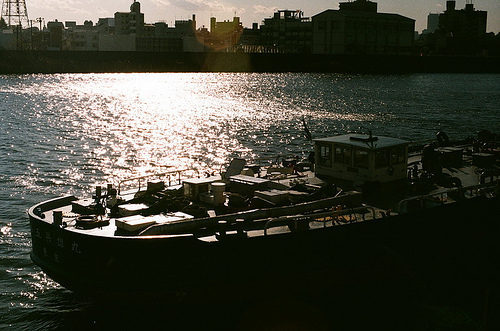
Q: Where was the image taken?
A: It was taken at the river.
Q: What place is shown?
A: It is a river.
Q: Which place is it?
A: It is a river.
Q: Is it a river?
A: Yes, it is a river.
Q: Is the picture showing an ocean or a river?
A: It is showing a river.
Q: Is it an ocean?
A: No, it is a river.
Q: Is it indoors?
A: Yes, it is indoors.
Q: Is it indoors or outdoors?
A: It is indoors.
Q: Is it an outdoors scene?
A: No, it is indoors.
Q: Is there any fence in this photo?
A: No, there are no fences.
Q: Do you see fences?
A: No, there are no fences.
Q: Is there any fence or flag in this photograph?
A: No, there are no fences or flags.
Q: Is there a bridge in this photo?
A: No, there are no bridges.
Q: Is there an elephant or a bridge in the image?
A: No, there are no bridges or elephants.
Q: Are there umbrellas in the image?
A: No, there are no umbrellas.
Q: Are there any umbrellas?
A: No, there are no umbrellas.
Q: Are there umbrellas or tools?
A: No, there are no umbrellas or tools.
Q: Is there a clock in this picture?
A: No, there are no clocks.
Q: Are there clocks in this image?
A: No, there are no clocks.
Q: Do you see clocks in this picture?
A: No, there are no clocks.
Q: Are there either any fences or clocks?
A: No, there are no clocks or fences.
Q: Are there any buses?
A: No, there are no buses.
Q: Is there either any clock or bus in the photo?
A: No, there are no buses or clocks.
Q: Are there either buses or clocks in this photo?
A: No, there are no buses or clocks.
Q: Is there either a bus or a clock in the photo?
A: No, there are no buses or clocks.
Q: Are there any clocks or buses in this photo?
A: No, there are no buses or clocks.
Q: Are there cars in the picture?
A: No, there are no cars.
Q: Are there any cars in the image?
A: No, there are no cars.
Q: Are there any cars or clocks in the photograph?
A: No, there are no cars or clocks.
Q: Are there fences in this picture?
A: No, there are no fences.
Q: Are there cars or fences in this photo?
A: No, there are no fences or cars.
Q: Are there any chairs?
A: No, there are no chairs.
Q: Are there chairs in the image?
A: No, there are no chairs.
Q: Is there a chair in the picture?
A: No, there are no chairs.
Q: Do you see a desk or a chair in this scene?
A: No, there are no chairs or desks.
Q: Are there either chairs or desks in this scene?
A: No, there are no chairs or desks.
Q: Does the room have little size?
A: Yes, the room is little.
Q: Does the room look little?
A: Yes, the room is little.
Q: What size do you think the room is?
A: The room is little.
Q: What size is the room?
A: The room is little.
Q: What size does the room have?
A: The room has little size.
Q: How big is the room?
A: The room is little.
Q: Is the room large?
A: No, the room is little.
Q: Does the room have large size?
A: No, the room is little.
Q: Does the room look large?
A: No, the room is little.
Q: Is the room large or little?
A: The room is little.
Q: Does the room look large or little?
A: The room is little.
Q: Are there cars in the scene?
A: No, there are no cars.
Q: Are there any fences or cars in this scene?
A: No, there are no cars or fences.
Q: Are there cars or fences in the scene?
A: No, there are no cars or fences.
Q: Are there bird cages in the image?
A: No, there are no bird cages.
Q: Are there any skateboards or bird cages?
A: No, there are no bird cages or skateboards.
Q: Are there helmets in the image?
A: No, there are no helmets.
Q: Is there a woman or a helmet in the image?
A: No, there are no helmets or women.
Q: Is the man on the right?
A: Yes, the man is on the right of the image.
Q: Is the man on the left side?
A: No, the man is on the right of the image.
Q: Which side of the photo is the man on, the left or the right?
A: The man is on the right of the image.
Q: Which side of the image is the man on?
A: The man is on the right of the image.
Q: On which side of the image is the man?
A: The man is on the right of the image.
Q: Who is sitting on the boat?
A: The man is sitting on the boat.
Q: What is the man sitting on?
A: The man is sitting on the boat.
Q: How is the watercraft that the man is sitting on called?
A: The watercraft is a boat.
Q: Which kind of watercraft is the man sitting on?
A: The man is sitting on the boat.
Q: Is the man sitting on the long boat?
A: Yes, the man is sitting on the boat.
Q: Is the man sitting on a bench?
A: No, the man is sitting on the boat.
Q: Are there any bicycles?
A: No, there are no bicycles.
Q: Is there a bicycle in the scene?
A: No, there are no bicycles.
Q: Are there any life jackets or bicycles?
A: No, there are no bicycles or life jackets.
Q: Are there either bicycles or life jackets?
A: No, there are no bicycles or life jackets.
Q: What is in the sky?
A: The clouds are in the sky.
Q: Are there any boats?
A: Yes, there is a boat.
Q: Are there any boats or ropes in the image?
A: Yes, there is a boat.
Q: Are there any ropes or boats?
A: Yes, there is a boat.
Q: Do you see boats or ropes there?
A: Yes, there is a boat.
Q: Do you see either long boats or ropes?
A: Yes, there is a long boat.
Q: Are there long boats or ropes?
A: Yes, there is a long boat.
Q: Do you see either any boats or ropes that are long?
A: Yes, the boat is long.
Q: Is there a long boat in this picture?
A: Yes, there is a long boat.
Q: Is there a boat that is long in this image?
A: Yes, there is a long boat.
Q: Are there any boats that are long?
A: Yes, there is a boat that is long.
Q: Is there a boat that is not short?
A: Yes, there is a long boat.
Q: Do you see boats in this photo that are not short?
A: Yes, there is a long boat.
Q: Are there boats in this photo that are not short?
A: Yes, there is a long boat.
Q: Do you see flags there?
A: No, there are no flags.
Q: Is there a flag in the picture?
A: No, there are no flags.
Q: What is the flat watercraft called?
A: The watercraft is a boat.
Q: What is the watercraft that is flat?
A: The watercraft is a boat.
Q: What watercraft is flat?
A: The watercraft is a boat.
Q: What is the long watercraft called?
A: The watercraft is a boat.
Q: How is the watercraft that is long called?
A: The watercraft is a boat.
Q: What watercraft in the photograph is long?
A: The watercraft is a boat.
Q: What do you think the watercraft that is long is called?
A: The watercraft is a boat.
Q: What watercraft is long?
A: The watercraft is a boat.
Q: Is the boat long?
A: Yes, the boat is long.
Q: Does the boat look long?
A: Yes, the boat is long.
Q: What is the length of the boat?
A: The boat is long.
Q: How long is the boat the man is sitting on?
A: The boat is long.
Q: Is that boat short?
A: No, the boat is long.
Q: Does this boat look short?
A: No, the boat is long.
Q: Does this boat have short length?
A: No, the boat is long.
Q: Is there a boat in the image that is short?
A: No, there is a boat but it is long.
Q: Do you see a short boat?
A: No, there is a boat but it is long.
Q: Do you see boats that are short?
A: No, there is a boat but it is long.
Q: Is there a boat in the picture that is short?
A: No, there is a boat but it is long.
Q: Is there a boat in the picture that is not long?
A: No, there is a boat but it is long.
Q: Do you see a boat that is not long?
A: No, there is a boat but it is long.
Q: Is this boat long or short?
A: The boat is long.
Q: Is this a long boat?
A: Yes, this is a long boat.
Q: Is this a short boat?
A: No, this is a long boat.